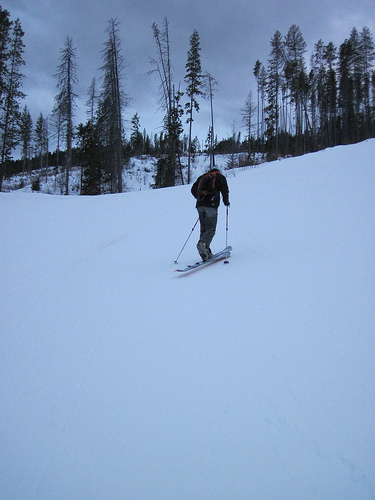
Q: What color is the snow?
A: White.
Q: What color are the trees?
A: Green.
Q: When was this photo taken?
A: During the day.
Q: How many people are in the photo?
A: One.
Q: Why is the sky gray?
A: It is cloudy.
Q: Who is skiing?
A: A man.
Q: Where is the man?
A: In the snow.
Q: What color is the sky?
A: Gray.